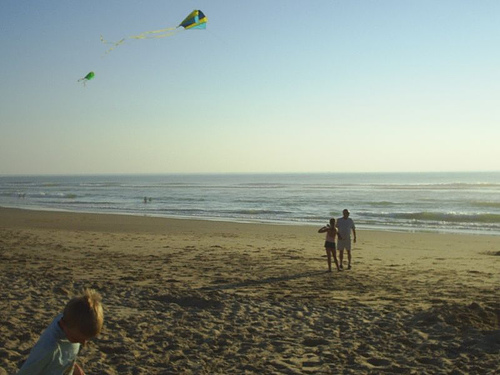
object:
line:
[0, 172, 500, 178]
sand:
[0, 205, 498, 372]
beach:
[0, 206, 498, 372]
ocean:
[0, 170, 500, 237]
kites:
[76, 8, 208, 87]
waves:
[215, 207, 294, 213]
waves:
[0, 175, 499, 237]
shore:
[0, 206, 499, 374]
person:
[318, 218, 342, 273]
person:
[14, 289, 107, 374]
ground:
[421, 135, 469, 171]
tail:
[99, 27, 182, 57]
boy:
[22, 288, 104, 375]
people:
[318, 209, 356, 273]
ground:
[0, 206, 499, 374]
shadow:
[151, 261, 333, 311]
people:
[326, 209, 357, 269]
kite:
[76, 9, 208, 88]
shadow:
[157, 244, 337, 297]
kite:
[99, 9, 207, 62]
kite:
[76, 71, 95, 89]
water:
[151, 173, 481, 204]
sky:
[0, 0, 499, 176]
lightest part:
[431, 144, 481, 172]